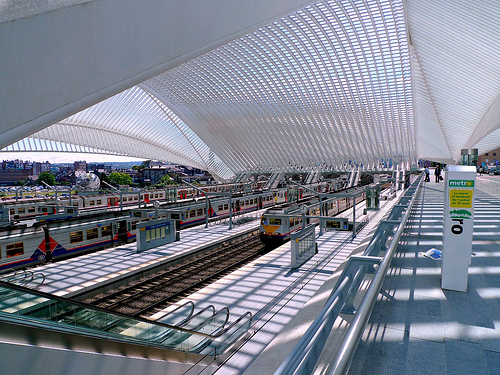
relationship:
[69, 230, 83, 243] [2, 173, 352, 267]
window on train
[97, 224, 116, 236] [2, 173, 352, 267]
window on train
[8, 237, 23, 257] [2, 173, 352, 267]
window on train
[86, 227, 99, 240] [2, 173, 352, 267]
window on train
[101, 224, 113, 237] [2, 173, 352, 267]
window on train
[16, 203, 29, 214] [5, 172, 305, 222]
window on train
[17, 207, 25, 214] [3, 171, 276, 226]
window on train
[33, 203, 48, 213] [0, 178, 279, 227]
window on train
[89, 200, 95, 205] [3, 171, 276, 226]
window on train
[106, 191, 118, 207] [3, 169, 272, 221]
window on train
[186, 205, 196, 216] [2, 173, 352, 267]
window on train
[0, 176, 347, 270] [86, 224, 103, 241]
window on train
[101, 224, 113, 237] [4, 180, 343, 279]
window on train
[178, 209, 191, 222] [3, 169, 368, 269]
window on train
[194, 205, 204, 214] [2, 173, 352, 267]
window on train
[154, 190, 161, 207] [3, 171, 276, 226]
window on train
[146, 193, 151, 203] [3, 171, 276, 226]
window on train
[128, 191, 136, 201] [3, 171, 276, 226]
window on train